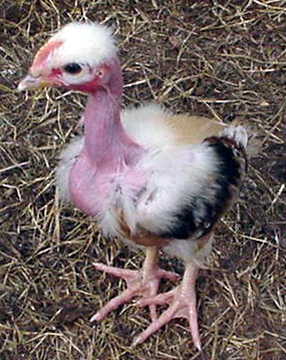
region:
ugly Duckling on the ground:
[17, 22, 250, 350]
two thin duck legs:
[79, 239, 211, 349]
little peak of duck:
[20, 67, 44, 90]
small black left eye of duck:
[57, 59, 78, 74]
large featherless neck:
[75, 59, 134, 205]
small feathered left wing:
[143, 130, 240, 237]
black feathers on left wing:
[155, 126, 252, 236]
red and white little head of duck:
[29, 21, 115, 93]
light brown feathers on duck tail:
[155, 104, 224, 144]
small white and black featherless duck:
[12, 18, 249, 348]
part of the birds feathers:
[172, 213, 195, 239]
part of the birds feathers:
[139, 213, 161, 237]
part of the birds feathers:
[211, 179, 227, 198]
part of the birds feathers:
[166, 173, 192, 195]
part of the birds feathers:
[170, 147, 202, 171]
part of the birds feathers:
[223, 130, 240, 166]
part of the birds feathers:
[138, 114, 158, 138]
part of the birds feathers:
[179, 119, 201, 139]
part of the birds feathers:
[58, 141, 76, 185]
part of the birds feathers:
[80, 35, 102, 53]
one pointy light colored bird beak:
[17, 69, 42, 91]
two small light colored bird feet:
[70, 250, 208, 352]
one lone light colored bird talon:
[88, 303, 114, 324]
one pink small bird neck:
[81, 91, 131, 162]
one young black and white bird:
[13, 19, 261, 350]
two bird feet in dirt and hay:
[72, 252, 221, 352]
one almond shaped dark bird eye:
[61, 60, 85, 77]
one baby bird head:
[15, 16, 119, 96]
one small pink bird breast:
[68, 167, 117, 220]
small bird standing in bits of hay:
[13, 15, 271, 350]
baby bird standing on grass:
[31, 29, 227, 276]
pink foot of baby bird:
[109, 253, 164, 316]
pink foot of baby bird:
[166, 250, 209, 330]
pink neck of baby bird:
[81, 79, 128, 154]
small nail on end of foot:
[89, 315, 97, 321]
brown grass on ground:
[11, 131, 280, 344]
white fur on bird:
[159, 195, 179, 217]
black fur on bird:
[173, 211, 198, 231]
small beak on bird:
[15, 69, 33, 93]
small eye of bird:
[61, 61, 88, 79]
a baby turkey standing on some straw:
[17, 21, 258, 349]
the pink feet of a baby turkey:
[86, 261, 203, 352]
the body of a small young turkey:
[60, 125, 250, 246]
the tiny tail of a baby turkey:
[221, 116, 253, 152]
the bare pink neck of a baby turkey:
[71, 90, 136, 164]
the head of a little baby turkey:
[17, 24, 119, 95]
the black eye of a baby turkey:
[62, 62, 82, 73]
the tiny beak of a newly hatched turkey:
[17, 74, 40, 91]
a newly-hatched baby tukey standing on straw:
[18, 22, 252, 354]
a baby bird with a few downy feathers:
[17, 23, 253, 351]